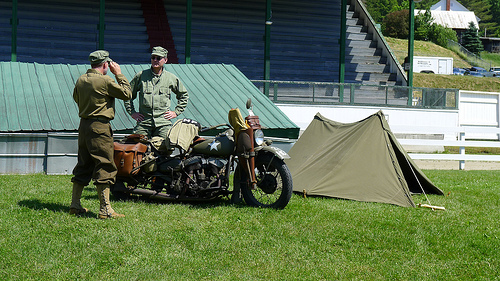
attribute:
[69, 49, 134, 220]
soldier — standing, saluting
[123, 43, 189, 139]
soldier — akimbo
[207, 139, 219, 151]
star — white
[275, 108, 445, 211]
tent — brown, green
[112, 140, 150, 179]
bag — brown, leather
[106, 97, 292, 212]
motorcycle — green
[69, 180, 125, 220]
boots — brown, tan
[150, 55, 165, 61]
sunglasses — black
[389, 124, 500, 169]
fence — white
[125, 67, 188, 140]
uniform — green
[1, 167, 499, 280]
grass — green, healthy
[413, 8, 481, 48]
house — far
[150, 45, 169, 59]
hat — green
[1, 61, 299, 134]
roof — green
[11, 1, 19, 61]
post — green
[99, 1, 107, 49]
post — green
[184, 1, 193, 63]
post — green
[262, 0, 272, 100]
post — green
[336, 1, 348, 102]
post — green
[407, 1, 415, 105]
post — green